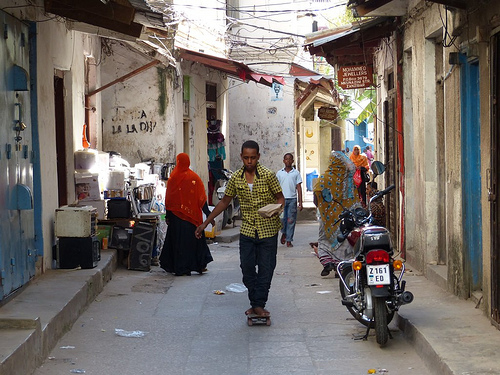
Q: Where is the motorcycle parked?
A: On the sidewalk.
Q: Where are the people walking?
A: On the sidewalk.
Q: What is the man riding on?
A: Skateboard.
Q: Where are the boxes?
A: Next to the building.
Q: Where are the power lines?
A: Above the buildings.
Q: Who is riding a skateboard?
A: The boy.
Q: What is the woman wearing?
A: Dress and scarf.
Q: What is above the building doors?
A: Awning.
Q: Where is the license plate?
A: On the back of the motorcycle.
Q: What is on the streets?
A: Trash.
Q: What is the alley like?
A: Paved.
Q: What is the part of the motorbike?
A: Back.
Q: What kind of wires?
A: Electric.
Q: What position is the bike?
A: Parked.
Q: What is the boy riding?
A: Skateboard.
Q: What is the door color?
A: Blue.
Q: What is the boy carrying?
A: Book.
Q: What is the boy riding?
A: Skateboard.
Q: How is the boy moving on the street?
A: Riding a skateboard.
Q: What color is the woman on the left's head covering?
A: Red.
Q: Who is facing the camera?
A: Two boys.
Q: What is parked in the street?
A: Motorcycle.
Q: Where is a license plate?
A: Back of the motorcycle.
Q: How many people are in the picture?
A: Five.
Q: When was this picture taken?
A: Daytime.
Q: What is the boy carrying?
A: Small box.